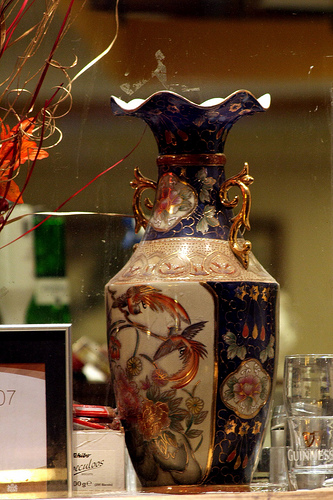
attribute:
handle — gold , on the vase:
[220, 160, 256, 264]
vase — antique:
[96, 83, 279, 486]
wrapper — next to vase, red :
[71, 401, 110, 417]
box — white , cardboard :
[69, 429, 126, 493]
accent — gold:
[130, 166, 156, 234]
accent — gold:
[219, 160, 253, 270]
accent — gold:
[155, 153, 224, 165]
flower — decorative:
[0, 111, 48, 215]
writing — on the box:
[71, 452, 113, 486]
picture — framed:
[2, 323, 72, 498]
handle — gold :
[212, 179, 309, 279]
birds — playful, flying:
[104, 280, 206, 407]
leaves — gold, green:
[201, 202, 221, 233]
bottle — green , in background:
[282, 353, 331, 486]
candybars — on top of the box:
[72, 402, 122, 431]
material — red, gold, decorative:
[3, 3, 148, 247]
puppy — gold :
[102, 85, 280, 409]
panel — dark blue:
[197, 274, 278, 483]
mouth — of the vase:
[107, 89, 273, 112]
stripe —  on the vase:
[206, 415, 217, 468]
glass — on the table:
[273, 400, 328, 486]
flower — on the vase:
[108, 288, 218, 479]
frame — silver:
[2, 323, 74, 498]